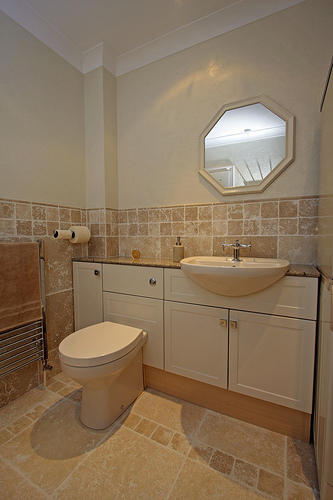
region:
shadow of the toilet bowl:
[25, 396, 128, 457]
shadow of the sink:
[178, 396, 312, 499]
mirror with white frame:
[194, 101, 298, 198]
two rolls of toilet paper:
[56, 223, 87, 243]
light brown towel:
[1, 240, 43, 327]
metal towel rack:
[2, 236, 50, 365]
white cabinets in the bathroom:
[73, 262, 312, 406]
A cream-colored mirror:
[192, 93, 299, 200]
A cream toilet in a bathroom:
[56, 318, 147, 431]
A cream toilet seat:
[54, 320, 144, 368]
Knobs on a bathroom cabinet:
[215, 316, 238, 329]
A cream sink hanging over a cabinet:
[178, 239, 291, 301]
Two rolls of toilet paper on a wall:
[53, 225, 91, 244]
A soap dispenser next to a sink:
[168, 234, 187, 263]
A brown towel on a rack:
[4, 239, 43, 333]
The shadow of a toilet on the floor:
[26, 398, 114, 462]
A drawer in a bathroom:
[96, 259, 166, 301]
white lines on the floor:
[91, 457, 117, 475]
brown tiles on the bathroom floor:
[136, 419, 184, 445]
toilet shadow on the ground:
[30, 402, 110, 462]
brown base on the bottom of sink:
[159, 371, 224, 401]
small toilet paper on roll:
[46, 226, 75, 247]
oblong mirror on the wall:
[181, 91, 307, 199]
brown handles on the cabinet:
[207, 315, 241, 328]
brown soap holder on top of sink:
[163, 234, 195, 263]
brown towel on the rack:
[5, 264, 39, 300]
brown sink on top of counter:
[182, 235, 293, 300]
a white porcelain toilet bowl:
[57, 320, 149, 429]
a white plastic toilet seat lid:
[56, 321, 142, 367]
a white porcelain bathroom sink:
[180, 253, 289, 295]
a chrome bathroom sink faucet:
[220, 238, 252, 259]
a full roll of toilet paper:
[68, 224, 91, 244]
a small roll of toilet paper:
[52, 229, 71, 239]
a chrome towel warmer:
[0, 238, 49, 384]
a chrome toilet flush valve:
[146, 278, 156, 287]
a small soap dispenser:
[171, 235, 185, 262]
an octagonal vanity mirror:
[196, 94, 296, 195]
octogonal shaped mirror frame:
[196, 91, 296, 197]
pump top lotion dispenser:
[171, 234, 185, 263]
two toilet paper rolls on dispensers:
[51, 224, 92, 244]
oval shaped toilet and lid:
[56, 318, 147, 430]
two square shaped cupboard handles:
[217, 317, 237, 329]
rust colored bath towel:
[0, 235, 43, 332]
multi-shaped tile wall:
[0, 192, 331, 407]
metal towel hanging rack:
[0, 240, 55, 378]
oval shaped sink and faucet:
[178, 237, 291, 300]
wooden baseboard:
[141, 363, 312, 445]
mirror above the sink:
[199, 96, 291, 194]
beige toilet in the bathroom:
[54, 320, 154, 435]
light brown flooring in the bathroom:
[7, 374, 326, 496]